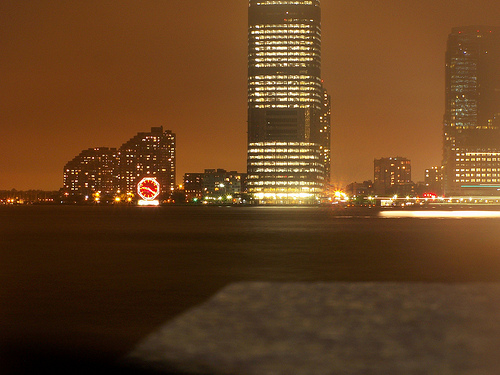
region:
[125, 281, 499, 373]
a large stone object in the foreground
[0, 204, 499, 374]
a large body of water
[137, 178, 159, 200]
a large red illuminated clock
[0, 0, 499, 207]
a city skyline in the background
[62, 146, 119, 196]
a large housing building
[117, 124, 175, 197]
another large housing building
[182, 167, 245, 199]
a group of medium-sized buildings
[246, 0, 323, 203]
a tall skyscraper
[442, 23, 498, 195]
a tall skyscraper in the background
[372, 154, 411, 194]
a large building in the background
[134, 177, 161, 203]
a red and white light up clock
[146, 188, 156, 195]
the white minute hand of a clock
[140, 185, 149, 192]
the white and glowing hour hand of a clock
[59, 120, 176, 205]
a couple of buildings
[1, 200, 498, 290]
part of the water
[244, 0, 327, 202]
a very tall building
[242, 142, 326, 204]
the bottom of a building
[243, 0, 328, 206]
a building with a lot of office lights on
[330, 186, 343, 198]
a very bright street light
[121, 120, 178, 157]
the top of a building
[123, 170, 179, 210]
large round white clock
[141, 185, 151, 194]
orange base on clock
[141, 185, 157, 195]
white hands on clock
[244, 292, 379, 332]
gray asphalt on top of wide cover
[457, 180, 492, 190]
green light on front of building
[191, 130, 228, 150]
orange glow in the sky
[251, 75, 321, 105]
lights in the building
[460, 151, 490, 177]
windows in the building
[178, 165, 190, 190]
frame on side of building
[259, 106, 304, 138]
parking lots in middle of building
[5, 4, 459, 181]
dark sky of night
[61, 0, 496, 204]
lights of city skyline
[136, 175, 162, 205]
illuminated red and clock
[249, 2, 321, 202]
lights on skyscraper side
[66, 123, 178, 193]
building with uneven roof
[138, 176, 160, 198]
white hands on clock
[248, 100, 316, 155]
dark section of building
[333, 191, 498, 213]
streetlights on horizon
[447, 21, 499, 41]
red lights on top of building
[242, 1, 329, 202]
tallest building on skyline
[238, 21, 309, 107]
Lights on the building.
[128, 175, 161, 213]
Clock in front of the building.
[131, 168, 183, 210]
Clock is red.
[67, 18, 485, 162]
It is night time.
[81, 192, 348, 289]
Water on the side of buildings.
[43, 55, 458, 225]
A city at night.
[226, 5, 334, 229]
Tall buildings with lights.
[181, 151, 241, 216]
Small building with lights.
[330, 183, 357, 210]
The light is shiny.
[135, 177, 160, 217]
The clock is bright.